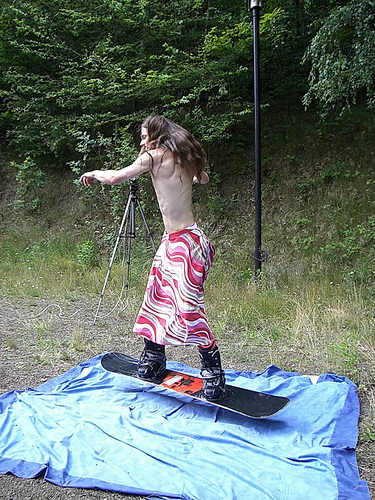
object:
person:
[77, 111, 226, 403]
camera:
[93, 175, 157, 323]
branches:
[299, 1, 375, 134]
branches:
[190, 1, 247, 166]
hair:
[141, 112, 207, 193]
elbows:
[105, 168, 123, 188]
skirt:
[130, 221, 217, 348]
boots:
[197, 346, 226, 401]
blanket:
[0, 349, 370, 499]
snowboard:
[98, 348, 291, 423]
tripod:
[91, 197, 159, 325]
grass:
[267, 235, 375, 362]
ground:
[0, 237, 99, 496]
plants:
[8, 154, 48, 215]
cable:
[17, 302, 81, 320]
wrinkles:
[58, 364, 104, 396]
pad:
[301, 374, 321, 386]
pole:
[249, 0, 263, 288]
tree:
[6, 1, 77, 161]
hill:
[0, 26, 373, 209]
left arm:
[76, 148, 154, 188]